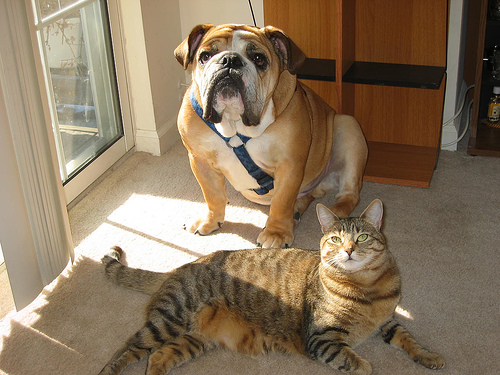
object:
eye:
[330, 235, 342, 244]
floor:
[9, 155, 500, 374]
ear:
[315, 203, 340, 235]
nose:
[219, 52, 247, 70]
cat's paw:
[426, 352, 446, 370]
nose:
[343, 241, 354, 255]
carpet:
[409, 193, 500, 328]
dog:
[171, 22, 369, 249]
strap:
[189, 90, 274, 195]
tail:
[101, 245, 169, 296]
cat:
[100, 198, 452, 374]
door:
[19, 0, 134, 214]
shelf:
[265, 0, 449, 189]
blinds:
[0, 3, 79, 313]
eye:
[355, 233, 369, 243]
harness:
[190, 95, 273, 196]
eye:
[247, 45, 269, 73]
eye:
[197, 46, 216, 65]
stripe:
[311, 324, 349, 337]